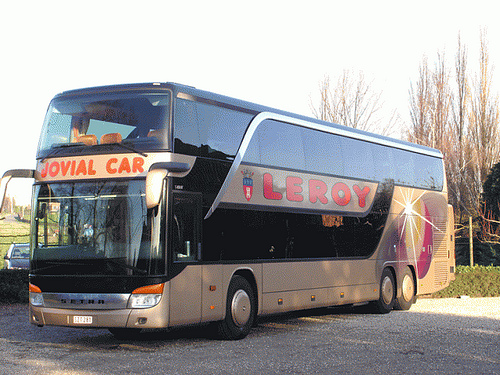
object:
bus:
[0, 81, 458, 340]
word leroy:
[261, 169, 372, 208]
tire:
[218, 277, 255, 340]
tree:
[307, 68, 378, 132]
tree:
[399, 31, 499, 269]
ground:
[0, 284, 499, 374]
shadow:
[1, 299, 499, 374]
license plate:
[72, 315, 93, 324]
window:
[28, 181, 161, 276]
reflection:
[44, 184, 151, 264]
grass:
[0, 222, 26, 246]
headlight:
[29, 291, 45, 307]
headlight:
[130, 293, 163, 310]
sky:
[0, 2, 136, 63]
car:
[3, 242, 45, 271]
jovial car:
[37, 156, 149, 178]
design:
[241, 169, 257, 202]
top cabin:
[35, 82, 456, 212]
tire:
[376, 268, 397, 315]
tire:
[392, 267, 414, 311]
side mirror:
[144, 162, 191, 208]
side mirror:
[0, 166, 37, 221]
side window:
[174, 97, 252, 159]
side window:
[172, 191, 205, 261]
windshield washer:
[28, 261, 85, 275]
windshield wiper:
[92, 252, 147, 275]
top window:
[40, 96, 174, 150]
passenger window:
[214, 208, 285, 260]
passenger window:
[277, 215, 376, 260]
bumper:
[26, 307, 168, 329]